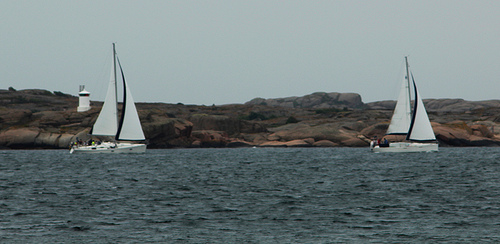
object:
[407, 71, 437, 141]
sail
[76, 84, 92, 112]
building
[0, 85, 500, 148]
mountain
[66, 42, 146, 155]
boat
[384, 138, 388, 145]
someone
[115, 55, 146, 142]
white sail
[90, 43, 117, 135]
white sail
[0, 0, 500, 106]
clouds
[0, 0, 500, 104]
sky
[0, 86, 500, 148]
ground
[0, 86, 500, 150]
rocks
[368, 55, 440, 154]
boat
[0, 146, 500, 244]
water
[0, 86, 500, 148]
land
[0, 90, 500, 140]
body